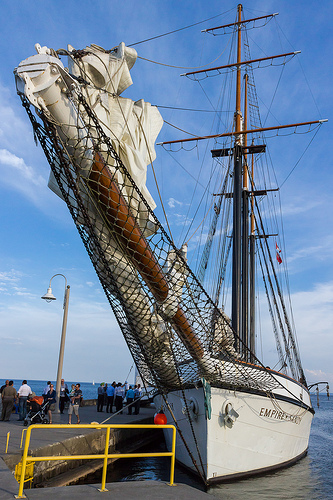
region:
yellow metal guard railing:
[7, 419, 191, 497]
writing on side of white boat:
[256, 405, 305, 431]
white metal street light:
[37, 272, 64, 308]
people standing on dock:
[2, 373, 148, 436]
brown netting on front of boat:
[96, 215, 251, 389]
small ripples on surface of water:
[282, 467, 323, 498]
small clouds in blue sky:
[2, 264, 38, 334]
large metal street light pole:
[54, 283, 76, 419]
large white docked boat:
[118, 287, 324, 490]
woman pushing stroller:
[20, 382, 65, 435]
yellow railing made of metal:
[6, 416, 181, 499]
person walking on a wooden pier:
[66, 381, 85, 425]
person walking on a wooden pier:
[41, 382, 56, 427]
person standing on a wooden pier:
[14, 377, 32, 425]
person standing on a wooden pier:
[0, 377, 17, 429]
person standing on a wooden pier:
[93, 381, 105, 414]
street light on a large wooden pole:
[37, 270, 73, 413]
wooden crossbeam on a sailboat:
[198, 10, 280, 39]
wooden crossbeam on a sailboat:
[151, 114, 328, 156]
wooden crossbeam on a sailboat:
[178, 47, 303, 88]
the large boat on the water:
[12, 3, 329, 486]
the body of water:
[0, 379, 332, 499]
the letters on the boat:
[259, 407, 300, 424]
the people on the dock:
[0, 379, 141, 423]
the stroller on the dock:
[23, 395, 50, 424]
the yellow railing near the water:
[13, 424, 175, 498]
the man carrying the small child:
[67, 384, 83, 423]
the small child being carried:
[68, 383, 75, 404]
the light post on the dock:
[41, 273, 69, 413]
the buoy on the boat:
[153, 408, 166, 424]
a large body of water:
[0, 378, 332, 499]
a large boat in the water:
[12, 3, 328, 485]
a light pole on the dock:
[40, 273, 69, 414]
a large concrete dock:
[0, 397, 223, 498]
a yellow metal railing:
[13, 423, 176, 498]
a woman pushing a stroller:
[45, 384, 56, 424]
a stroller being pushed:
[23, 395, 48, 425]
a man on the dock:
[16, 379, 32, 420]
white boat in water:
[157, 356, 313, 484]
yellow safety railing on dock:
[14, 423, 175, 492]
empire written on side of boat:
[258, 406, 285, 419]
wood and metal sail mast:
[232, 3, 257, 365]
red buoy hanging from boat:
[152, 408, 167, 424]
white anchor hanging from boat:
[222, 403, 239, 429]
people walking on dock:
[3, 376, 139, 423]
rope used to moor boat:
[99, 387, 153, 423]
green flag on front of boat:
[198, 375, 213, 423]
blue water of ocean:
[6, 378, 331, 491]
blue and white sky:
[12, 218, 93, 345]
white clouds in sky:
[14, 306, 49, 353]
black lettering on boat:
[240, 393, 306, 427]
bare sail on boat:
[162, 45, 298, 374]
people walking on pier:
[0, 363, 137, 448]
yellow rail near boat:
[10, 413, 186, 496]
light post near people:
[35, 271, 86, 415]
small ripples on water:
[239, 473, 317, 495]